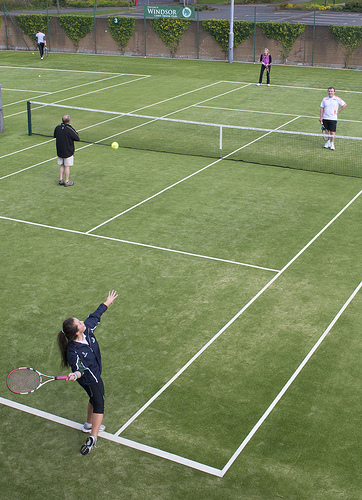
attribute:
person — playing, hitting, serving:
[56, 288, 120, 458]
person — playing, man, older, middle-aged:
[52, 112, 80, 189]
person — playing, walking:
[34, 27, 46, 59]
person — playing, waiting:
[255, 47, 273, 87]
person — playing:
[317, 85, 346, 149]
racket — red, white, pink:
[6, 365, 68, 397]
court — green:
[0, 49, 362, 498]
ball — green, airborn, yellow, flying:
[108, 140, 120, 151]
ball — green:
[37, 72, 41, 78]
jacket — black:
[52, 124, 80, 158]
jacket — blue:
[65, 301, 109, 383]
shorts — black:
[322, 118, 338, 132]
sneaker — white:
[80, 436, 98, 458]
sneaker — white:
[82, 423, 107, 433]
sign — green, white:
[144, 5, 194, 20]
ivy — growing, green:
[17, 14, 51, 40]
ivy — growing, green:
[56, 13, 94, 47]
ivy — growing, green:
[106, 16, 136, 50]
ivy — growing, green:
[147, 17, 189, 54]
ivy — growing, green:
[200, 17, 253, 55]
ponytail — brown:
[56, 327, 71, 371]